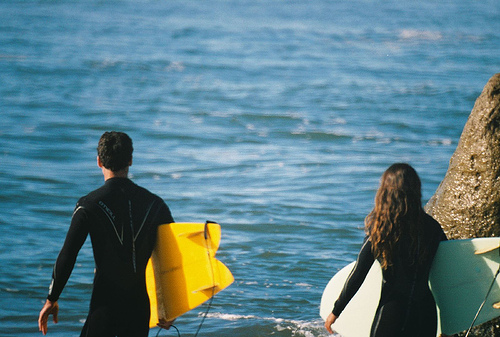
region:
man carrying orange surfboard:
[30, 127, 241, 335]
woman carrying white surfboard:
[314, 155, 496, 335]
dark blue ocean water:
[2, 1, 494, 332]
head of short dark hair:
[85, 124, 140, 181]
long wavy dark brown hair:
[357, 158, 435, 255]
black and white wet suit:
[41, 173, 179, 335]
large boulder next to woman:
[417, 61, 498, 236]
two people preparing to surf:
[18, 100, 474, 330]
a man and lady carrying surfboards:
[20, 111, 470, 327]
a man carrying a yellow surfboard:
[15, 95, 285, 320]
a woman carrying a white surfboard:
[287, 145, 497, 335]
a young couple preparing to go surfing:
[16, 80, 483, 327]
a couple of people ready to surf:
[17, 106, 477, 321]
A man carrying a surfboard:
[22, 107, 255, 329]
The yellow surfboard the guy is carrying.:
[156, 221, 233, 311]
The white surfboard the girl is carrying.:
[317, 239, 498, 329]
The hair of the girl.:
[362, 163, 429, 265]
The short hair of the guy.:
[97, 132, 133, 173]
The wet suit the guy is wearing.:
[52, 181, 172, 336]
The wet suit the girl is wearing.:
[331, 216, 438, 333]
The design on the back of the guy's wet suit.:
[92, 194, 152, 271]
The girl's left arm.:
[327, 237, 373, 329]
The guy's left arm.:
[42, 208, 88, 298]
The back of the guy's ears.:
[97, 152, 134, 169]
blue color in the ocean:
[214, 112, 316, 174]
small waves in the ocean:
[232, 309, 303, 323]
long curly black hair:
[365, 159, 428, 233]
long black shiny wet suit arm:
[324, 236, 375, 318]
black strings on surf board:
[196, 209, 231, 243]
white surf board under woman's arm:
[426, 235, 491, 335]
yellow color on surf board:
[163, 215, 244, 317]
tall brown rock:
[453, 145, 488, 207]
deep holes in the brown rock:
[451, 152, 481, 202]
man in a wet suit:
[37, 129, 176, 335]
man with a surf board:
[37, 130, 235, 335]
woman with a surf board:
[319, 162, 499, 334]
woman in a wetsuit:
[323, 161, 449, 335]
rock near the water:
[422, 72, 499, 335]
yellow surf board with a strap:
[144, 222, 233, 327]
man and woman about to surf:
[37, 130, 497, 335]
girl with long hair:
[325, 160, 449, 335]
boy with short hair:
[39, 129, 175, 335]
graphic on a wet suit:
[97, 196, 158, 272]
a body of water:
[4, 8, 449, 329]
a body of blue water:
[4, 6, 496, 331]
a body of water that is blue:
[0, 1, 495, 323]